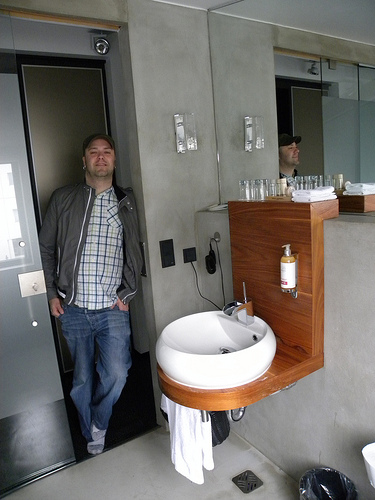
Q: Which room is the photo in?
A: It is at the bathroom.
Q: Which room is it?
A: It is a bathroom.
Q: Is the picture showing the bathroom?
A: Yes, it is showing the bathroom.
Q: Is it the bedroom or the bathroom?
A: It is the bathroom.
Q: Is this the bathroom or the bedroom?
A: It is the bathroom.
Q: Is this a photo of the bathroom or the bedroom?
A: It is showing the bathroom.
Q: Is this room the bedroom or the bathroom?
A: It is the bathroom.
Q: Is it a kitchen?
A: No, it is a bathroom.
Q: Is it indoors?
A: Yes, it is indoors.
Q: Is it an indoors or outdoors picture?
A: It is indoors.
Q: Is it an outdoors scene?
A: No, it is indoors.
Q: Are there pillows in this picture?
A: No, there are no pillows.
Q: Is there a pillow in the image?
A: No, there are no pillows.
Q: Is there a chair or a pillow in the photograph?
A: No, there are no pillows or chairs.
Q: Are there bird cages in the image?
A: No, there are no bird cages.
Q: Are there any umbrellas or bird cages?
A: No, there are no bird cages or umbrellas.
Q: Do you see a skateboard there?
A: No, there are no skateboards.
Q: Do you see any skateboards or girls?
A: No, there are no skateboards or girls.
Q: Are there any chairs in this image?
A: No, there are no chairs.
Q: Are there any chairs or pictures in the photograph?
A: No, there are no chairs or pictures.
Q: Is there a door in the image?
A: Yes, there is a door.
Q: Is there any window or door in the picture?
A: Yes, there is a door.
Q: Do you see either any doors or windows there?
A: Yes, there is a door.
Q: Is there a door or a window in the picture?
A: Yes, there is a door.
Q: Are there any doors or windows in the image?
A: Yes, there is a door.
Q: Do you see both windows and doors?
A: No, there is a door but no windows.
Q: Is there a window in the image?
A: No, there are no windows.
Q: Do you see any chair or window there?
A: No, there are no windows or chairs.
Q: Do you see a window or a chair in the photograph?
A: No, there are no windows or chairs.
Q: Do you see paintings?
A: No, there are no paintings.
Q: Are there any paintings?
A: No, there are no paintings.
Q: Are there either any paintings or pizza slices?
A: No, there are no paintings or pizza slices.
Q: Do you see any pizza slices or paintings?
A: No, there are no paintings or pizza slices.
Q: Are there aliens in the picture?
A: No, there are no aliens.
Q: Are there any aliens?
A: No, there are no aliens.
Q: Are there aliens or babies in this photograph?
A: No, there are no aliens or babies.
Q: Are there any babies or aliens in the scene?
A: No, there are no aliens or babies.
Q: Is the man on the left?
A: Yes, the man is on the left of the image.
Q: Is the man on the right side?
A: No, the man is on the left of the image.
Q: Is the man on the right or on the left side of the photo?
A: The man is on the left of the image.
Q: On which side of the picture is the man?
A: The man is on the left of the image.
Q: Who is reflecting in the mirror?
A: The man is reflecting in the mirror.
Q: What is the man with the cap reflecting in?
A: The man is reflecting in the mirror.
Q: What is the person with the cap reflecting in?
A: The man is reflecting in the mirror.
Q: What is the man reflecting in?
A: The man is reflecting in the mirror.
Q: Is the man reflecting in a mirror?
A: Yes, the man is reflecting in a mirror.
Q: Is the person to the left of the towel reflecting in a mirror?
A: Yes, the man is reflecting in a mirror.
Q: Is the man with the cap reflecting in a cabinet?
A: No, the man is reflecting in a mirror.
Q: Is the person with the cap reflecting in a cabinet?
A: No, the man is reflecting in a mirror.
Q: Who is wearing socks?
A: The man is wearing socks.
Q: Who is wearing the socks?
A: The man is wearing socks.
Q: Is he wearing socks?
A: Yes, the man is wearing socks.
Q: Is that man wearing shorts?
A: No, the man is wearing socks.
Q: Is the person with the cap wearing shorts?
A: No, the man is wearing socks.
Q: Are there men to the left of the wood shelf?
A: Yes, there is a man to the left of the shelf.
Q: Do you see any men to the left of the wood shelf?
A: Yes, there is a man to the left of the shelf.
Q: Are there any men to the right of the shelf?
A: No, the man is to the left of the shelf.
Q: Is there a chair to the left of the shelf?
A: No, there is a man to the left of the shelf.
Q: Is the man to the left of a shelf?
A: Yes, the man is to the left of a shelf.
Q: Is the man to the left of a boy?
A: No, the man is to the left of a shelf.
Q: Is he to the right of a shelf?
A: No, the man is to the left of a shelf.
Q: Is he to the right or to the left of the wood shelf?
A: The man is to the left of the shelf.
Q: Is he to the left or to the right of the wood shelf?
A: The man is to the left of the shelf.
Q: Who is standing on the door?
A: The man is standing on the door.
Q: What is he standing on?
A: The man is standing on the door.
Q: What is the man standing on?
A: The man is standing on the door.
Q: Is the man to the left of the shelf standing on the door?
A: Yes, the man is standing on the door.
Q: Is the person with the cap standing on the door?
A: Yes, the man is standing on the door.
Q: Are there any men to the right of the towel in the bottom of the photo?
A: No, the man is to the left of the towel.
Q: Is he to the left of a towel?
A: Yes, the man is to the left of a towel.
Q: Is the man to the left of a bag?
A: No, the man is to the left of a towel.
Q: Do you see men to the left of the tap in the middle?
A: Yes, there is a man to the left of the tap.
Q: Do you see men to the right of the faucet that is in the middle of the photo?
A: No, the man is to the left of the faucet.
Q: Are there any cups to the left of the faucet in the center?
A: No, there is a man to the left of the faucet.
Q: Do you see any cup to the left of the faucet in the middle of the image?
A: No, there is a man to the left of the faucet.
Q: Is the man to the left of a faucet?
A: Yes, the man is to the left of a faucet.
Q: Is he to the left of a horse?
A: No, the man is to the left of a faucet.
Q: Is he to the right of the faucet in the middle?
A: No, the man is to the left of the tap.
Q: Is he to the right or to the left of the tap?
A: The man is to the left of the tap.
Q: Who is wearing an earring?
A: The man is wearing an earring.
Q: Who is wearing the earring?
A: The man is wearing an earring.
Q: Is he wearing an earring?
A: Yes, the man is wearing an earring.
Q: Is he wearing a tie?
A: No, the man is wearing an earring.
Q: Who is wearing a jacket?
A: The man is wearing a jacket.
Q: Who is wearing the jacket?
A: The man is wearing a jacket.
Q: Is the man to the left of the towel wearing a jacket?
A: Yes, the man is wearing a jacket.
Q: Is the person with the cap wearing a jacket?
A: Yes, the man is wearing a jacket.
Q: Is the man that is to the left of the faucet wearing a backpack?
A: No, the man is wearing a jacket.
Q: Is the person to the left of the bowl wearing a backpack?
A: No, the man is wearing a jacket.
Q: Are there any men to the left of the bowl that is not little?
A: Yes, there is a man to the left of the bowl.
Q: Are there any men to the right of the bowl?
A: No, the man is to the left of the bowl.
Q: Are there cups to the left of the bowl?
A: No, there is a man to the left of the bowl.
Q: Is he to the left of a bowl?
A: Yes, the man is to the left of a bowl.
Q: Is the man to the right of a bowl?
A: No, the man is to the left of a bowl.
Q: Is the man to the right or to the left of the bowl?
A: The man is to the left of the bowl.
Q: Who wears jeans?
A: The man wears jeans.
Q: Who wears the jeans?
A: The man wears jeans.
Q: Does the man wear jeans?
A: Yes, the man wears jeans.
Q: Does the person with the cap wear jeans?
A: Yes, the man wears jeans.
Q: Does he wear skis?
A: No, the man wears jeans.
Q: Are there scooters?
A: No, there are no scooters.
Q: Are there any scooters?
A: No, there are no scooters.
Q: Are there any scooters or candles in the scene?
A: No, there are no scooters or candles.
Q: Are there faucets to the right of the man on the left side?
A: Yes, there is a faucet to the right of the man.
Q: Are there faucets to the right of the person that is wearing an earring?
A: Yes, there is a faucet to the right of the man.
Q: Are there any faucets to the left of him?
A: No, the faucet is to the right of the man.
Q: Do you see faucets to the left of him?
A: No, the faucet is to the right of the man.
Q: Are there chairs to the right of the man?
A: No, there is a faucet to the right of the man.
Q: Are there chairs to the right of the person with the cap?
A: No, there is a faucet to the right of the man.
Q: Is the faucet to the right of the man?
A: Yes, the faucet is to the right of the man.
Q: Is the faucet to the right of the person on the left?
A: Yes, the faucet is to the right of the man.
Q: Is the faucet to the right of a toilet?
A: No, the faucet is to the right of the man.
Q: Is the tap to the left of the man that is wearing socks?
A: No, the tap is to the right of the man.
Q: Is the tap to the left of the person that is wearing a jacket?
A: No, the tap is to the right of the man.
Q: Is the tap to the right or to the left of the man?
A: The tap is to the right of the man.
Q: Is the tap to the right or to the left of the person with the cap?
A: The tap is to the right of the man.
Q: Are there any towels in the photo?
A: Yes, there is a towel.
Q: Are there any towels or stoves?
A: Yes, there is a towel.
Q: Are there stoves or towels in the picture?
A: Yes, there is a towel.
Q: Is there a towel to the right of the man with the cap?
A: Yes, there is a towel to the right of the man.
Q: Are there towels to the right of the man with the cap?
A: Yes, there is a towel to the right of the man.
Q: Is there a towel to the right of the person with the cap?
A: Yes, there is a towel to the right of the man.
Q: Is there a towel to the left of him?
A: No, the towel is to the right of the man.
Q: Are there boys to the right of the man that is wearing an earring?
A: No, there is a towel to the right of the man.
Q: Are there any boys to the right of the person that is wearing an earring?
A: No, there is a towel to the right of the man.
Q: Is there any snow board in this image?
A: No, there are no snowboards.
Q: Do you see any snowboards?
A: No, there are no snowboards.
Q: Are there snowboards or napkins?
A: No, there are no snowboards or napkins.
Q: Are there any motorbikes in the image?
A: No, there are no motorbikes.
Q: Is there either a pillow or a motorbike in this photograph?
A: No, there are no motorcycles or pillows.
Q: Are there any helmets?
A: No, there are no helmets.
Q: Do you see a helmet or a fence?
A: No, there are no helmets or fences.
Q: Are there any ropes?
A: No, there are no ropes.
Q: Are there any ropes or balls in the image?
A: No, there are no ropes or balls.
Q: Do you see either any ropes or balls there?
A: No, there are no ropes or balls.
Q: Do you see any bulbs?
A: No, there are no bulbs.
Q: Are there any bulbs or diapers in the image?
A: No, there are no bulbs or diapers.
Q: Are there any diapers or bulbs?
A: No, there are no bulbs or diapers.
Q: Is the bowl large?
A: Yes, the bowl is large.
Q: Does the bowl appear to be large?
A: Yes, the bowl is large.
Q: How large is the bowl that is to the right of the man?
A: The bowl is large.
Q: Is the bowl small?
A: No, the bowl is large.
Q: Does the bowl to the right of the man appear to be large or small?
A: The bowl is large.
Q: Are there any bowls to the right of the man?
A: Yes, there is a bowl to the right of the man.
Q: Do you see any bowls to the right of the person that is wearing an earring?
A: Yes, there is a bowl to the right of the man.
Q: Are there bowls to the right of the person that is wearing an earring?
A: Yes, there is a bowl to the right of the man.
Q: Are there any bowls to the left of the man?
A: No, the bowl is to the right of the man.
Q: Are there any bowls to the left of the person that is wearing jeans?
A: No, the bowl is to the right of the man.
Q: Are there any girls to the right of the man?
A: No, there is a bowl to the right of the man.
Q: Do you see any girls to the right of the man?
A: No, there is a bowl to the right of the man.